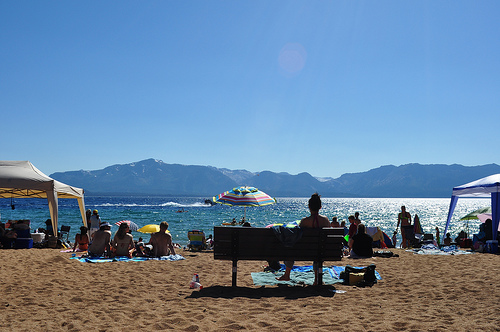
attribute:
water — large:
[3, 198, 493, 248]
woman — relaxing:
[276, 194, 331, 286]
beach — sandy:
[0, 248, 499, 331]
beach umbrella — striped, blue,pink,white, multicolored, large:
[213, 184, 276, 207]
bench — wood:
[213, 227, 345, 285]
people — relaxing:
[88, 221, 176, 258]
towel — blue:
[69, 255, 183, 264]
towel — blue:
[251, 266, 381, 284]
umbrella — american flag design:
[116, 219, 140, 233]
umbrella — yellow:
[139, 223, 170, 233]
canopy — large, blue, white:
[439, 174, 499, 245]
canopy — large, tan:
[1, 159, 88, 234]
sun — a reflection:
[276, 195, 492, 252]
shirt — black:
[351, 233, 373, 256]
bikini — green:
[399, 213, 411, 229]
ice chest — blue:
[16, 236, 33, 248]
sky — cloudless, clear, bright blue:
[1, 0, 499, 183]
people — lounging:
[46, 192, 492, 280]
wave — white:
[104, 201, 214, 209]